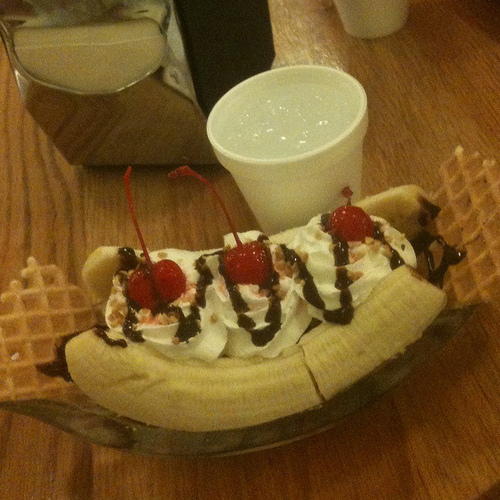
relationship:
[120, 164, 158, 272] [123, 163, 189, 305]
stem on cherry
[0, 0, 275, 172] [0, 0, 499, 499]
napkin holder on table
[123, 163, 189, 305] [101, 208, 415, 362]
cherry on whipped cream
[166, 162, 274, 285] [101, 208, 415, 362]
cherry on whipped cream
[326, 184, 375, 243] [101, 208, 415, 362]
cherry on whipped cream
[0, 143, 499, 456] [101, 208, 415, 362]
banana split with whipped cream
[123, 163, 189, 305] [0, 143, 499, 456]
cherry on banana split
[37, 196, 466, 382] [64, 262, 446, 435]
chocolate sauce on top of banana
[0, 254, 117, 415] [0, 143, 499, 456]
waffle cone on banana split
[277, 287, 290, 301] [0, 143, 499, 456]
peanut on banana split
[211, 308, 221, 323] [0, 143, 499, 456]
peanut on banana split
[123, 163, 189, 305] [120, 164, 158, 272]
cherry with stem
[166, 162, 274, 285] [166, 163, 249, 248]
cherry with stem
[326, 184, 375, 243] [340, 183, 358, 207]
cherry with stem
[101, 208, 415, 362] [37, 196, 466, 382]
whipped cream with chocolate sauce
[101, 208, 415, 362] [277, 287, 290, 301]
whipped cream with peanut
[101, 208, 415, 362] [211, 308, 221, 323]
whipped cream with peanut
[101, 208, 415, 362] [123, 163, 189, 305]
whipped cream with cherry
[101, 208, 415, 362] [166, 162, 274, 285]
whipped cream with cherry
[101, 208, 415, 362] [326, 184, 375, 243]
whipped cream with cherry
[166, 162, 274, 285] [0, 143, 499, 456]
cherry on banana split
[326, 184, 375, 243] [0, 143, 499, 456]
cherry on banana split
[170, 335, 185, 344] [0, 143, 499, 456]
peanut on banana split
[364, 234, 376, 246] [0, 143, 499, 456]
peanut on banana split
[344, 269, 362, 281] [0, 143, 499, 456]
peanut on banana split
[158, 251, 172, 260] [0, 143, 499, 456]
peanut on banana split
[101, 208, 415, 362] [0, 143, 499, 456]
whipped cream on banana split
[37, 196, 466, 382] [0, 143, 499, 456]
chocolate sauce on banana split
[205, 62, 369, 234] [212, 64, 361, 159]
cup has water